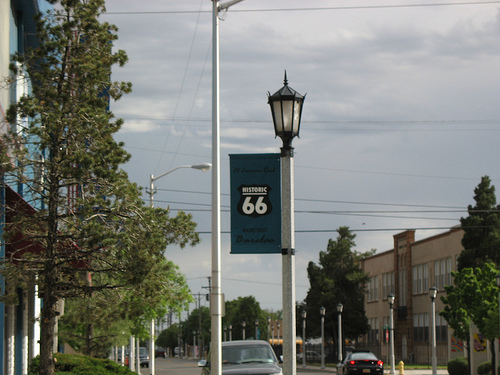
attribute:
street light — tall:
[267, 67, 306, 373]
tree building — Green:
[438, 175, 497, 373]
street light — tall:
[262, 67, 308, 374]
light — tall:
[229, 69, 324, 349]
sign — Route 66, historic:
[231, 149, 286, 259]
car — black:
[336, 348, 383, 372]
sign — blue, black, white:
[222, 148, 287, 257]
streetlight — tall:
[267, 70, 304, 370]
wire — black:
[140, 185, 467, 210]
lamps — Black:
[256, 53, 320, 173]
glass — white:
[258, 78, 316, 144]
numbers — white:
[241, 194, 268, 216]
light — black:
[262, 65, 309, 157]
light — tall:
[252, 316, 260, 338]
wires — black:
[147, 189, 465, 238]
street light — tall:
[237, 318, 249, 338]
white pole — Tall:
[209, 0, 224, 372]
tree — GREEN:
[0, 3, 205, 373]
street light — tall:
[144, 162, 214, 372]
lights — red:
[344, 356, 384, 372]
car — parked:
[211, 337, 282, 373]